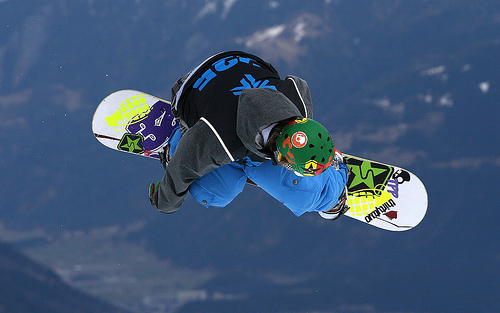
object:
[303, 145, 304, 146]
stickers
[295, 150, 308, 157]
green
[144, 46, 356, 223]
man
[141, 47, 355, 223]
stunt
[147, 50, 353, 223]
doing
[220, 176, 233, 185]
bright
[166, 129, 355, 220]
pants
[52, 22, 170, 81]
blurry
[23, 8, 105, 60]
scenery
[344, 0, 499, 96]
slightly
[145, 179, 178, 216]
glove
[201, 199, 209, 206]
small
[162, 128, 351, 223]
snowpants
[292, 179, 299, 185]
metal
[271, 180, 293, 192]
blue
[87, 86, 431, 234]
board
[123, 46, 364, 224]
riding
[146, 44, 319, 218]
jacket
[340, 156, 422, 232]
snow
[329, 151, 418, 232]
colorful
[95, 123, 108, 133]
white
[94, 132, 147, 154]
decorations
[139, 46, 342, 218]
baby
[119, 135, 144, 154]
star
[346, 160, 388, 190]
s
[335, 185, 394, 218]
grenade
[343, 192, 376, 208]
stencil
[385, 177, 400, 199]
letters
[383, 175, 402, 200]
tpp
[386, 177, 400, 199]
purple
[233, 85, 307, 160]
hood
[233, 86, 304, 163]
gray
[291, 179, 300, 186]
button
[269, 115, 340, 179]
helmet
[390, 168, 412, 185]
stickers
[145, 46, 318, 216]
hoodies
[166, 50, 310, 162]
vest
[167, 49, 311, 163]
grey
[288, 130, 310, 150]
sticker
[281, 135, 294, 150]
red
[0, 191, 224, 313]
background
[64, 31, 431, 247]
air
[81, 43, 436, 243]
flying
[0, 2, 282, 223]
mountain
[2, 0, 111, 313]
covered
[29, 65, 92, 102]
tops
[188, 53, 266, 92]
lettering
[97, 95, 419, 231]
designs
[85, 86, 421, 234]
snowboard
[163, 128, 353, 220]
light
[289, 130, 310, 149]
round